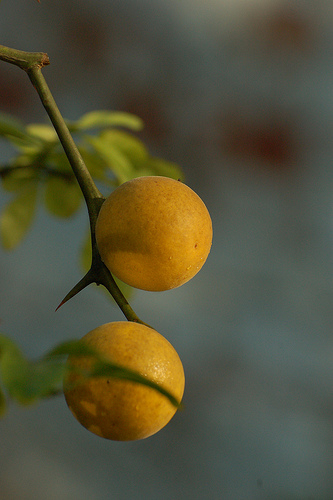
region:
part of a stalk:
[54, 116, 80, 159]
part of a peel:
[123, 407, 154, 451]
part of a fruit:
[122, 398, 159, 446]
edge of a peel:
[87, 419, 110, 455]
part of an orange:
[146, 376, 163, 388]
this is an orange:
[92, 172, 217, 276]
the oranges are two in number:
[85, 161, 173, 481]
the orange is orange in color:
[127, 216, 179, 257]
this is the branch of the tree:
[33, 65, 74, 136]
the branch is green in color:
[48, 103, 60, 124]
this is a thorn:
[51, 278, 84, 303]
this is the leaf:
[8, 176, 46, 228]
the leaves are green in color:
[76, 99, 122, 143]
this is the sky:
[234, 224, 322, 410]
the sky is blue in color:
[198, 19, 266, 101]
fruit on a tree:
[92, 171, 215, 301]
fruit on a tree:
[54, 317, 191, 444]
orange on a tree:
[54, 318, 190, 454]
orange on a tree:
[83, 169, 217, 302]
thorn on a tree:
[43, 266, 96, 318]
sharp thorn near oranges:
[42, 259, 100, 313]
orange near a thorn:
[59, 313, 183, 443]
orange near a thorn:
[81, 168, 219, 300]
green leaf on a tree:
[66, 101, 149, 138]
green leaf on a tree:
[88, 348, 186, 418]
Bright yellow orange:
[93, 168, 227, 286]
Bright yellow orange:
[61, 323, 192, 462]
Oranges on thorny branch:
[58, 146, 229, 480]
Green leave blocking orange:
[4, 340, 193, 407]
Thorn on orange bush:
[32, 262, 109, 315]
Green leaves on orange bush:
[6, 99, 203, 224]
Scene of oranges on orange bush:
[4, 23, 311, 482]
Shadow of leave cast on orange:
[89, 196, 165, 284]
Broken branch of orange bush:
[16, 32, 64, 86]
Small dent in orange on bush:
[72, 393, 110, 426]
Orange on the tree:
[100, 144, 208, 293]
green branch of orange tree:
[10, 42, 102, 207]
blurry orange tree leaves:
[3, 339, 84, 400]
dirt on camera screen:
[254, 466, 269, 493]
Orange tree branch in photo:
[15, 39, 199, 439]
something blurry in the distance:
[196, 75, 320, 183]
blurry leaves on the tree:
[72, 90, 191, 167]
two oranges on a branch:
[68, 150, 197, 493]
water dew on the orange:
[163, 249, 199, 268]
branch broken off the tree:
[17, 47, 58, 66]